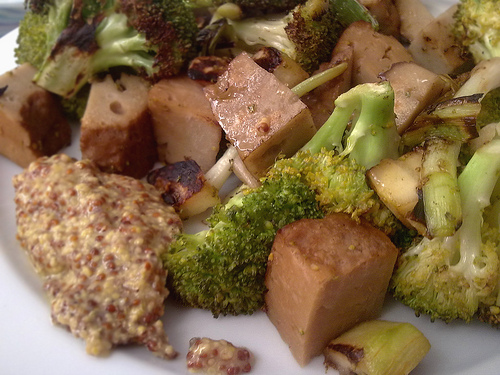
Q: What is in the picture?
A: Food.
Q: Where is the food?
A: On a plate.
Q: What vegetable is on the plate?
A: Broccoli.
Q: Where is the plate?
A: The table.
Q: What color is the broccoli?
A: Green.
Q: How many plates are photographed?
A: One.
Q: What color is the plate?
A: White.